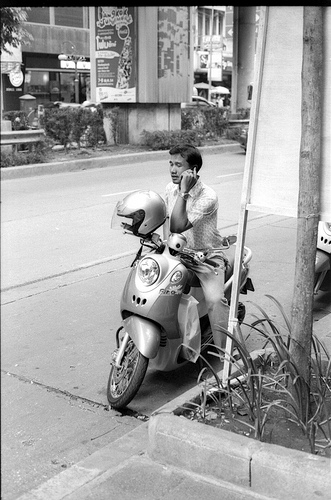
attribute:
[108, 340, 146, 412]
tire — black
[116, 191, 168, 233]
helmet — silver 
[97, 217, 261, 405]
scooter — silver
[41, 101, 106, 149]
bush — small 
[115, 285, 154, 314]
holes — black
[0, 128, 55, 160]
fence barrier — metal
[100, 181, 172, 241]
helmet — silver, black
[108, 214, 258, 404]
scooter — small 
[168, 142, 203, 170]
hair — short, black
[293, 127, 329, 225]
stump — skinny